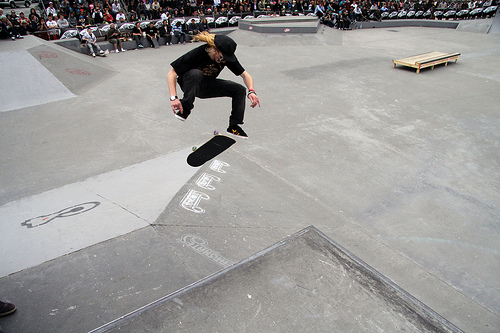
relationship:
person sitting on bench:
[105, 22, 122, 55] [65, 20, 320, 42]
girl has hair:
[168, 27, 263, 139] [194, 16, 216, 48]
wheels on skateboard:
[209, 125, 221, 141] [183, 130, 235, 167]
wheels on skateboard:
[185, 141, 197, 153] [183, 130, 235, 167]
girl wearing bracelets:
[168, 27, 263, 139] [245, 88, 255, 99]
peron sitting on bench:
[158, 17, 173, 47] [73, 29, 241, 54]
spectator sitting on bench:
[78, 22, 108, 56] [58, 25, 208, 64]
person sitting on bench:
[143, 18, 162, 45] [77, 37, 198, 52]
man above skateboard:
[167, 30, 261, 139] [188, 133, 228, 173]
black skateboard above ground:
[186, 130, 237, 168] [0, 125, 342, 330]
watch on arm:
[168, 93, 180, 102] [167, 45, 196, 116]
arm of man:
[167, 45, 196, 116] [166, 31, 261, 139]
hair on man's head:
[190, 30, 216, 47] [199, 25, 237, 64]